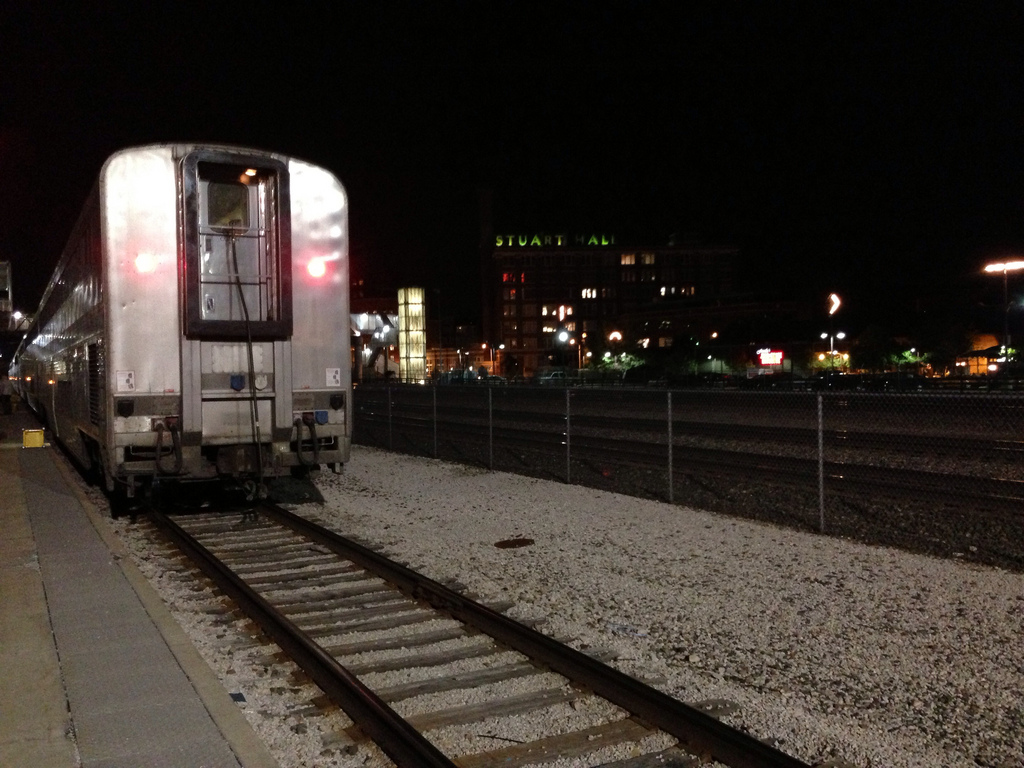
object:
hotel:
[476, 219, 748, 385]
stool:
[16, 421, 51, 454]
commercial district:
[351, 215, 1021, 392]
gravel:
[74, 449, 1021, 766]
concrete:
[132, 524, 284, 626]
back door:
[175, 150, 294, 453]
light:
[392, 276, 435, 393]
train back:
[101, 145, 356, 522]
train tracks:
[101, 505, 848, 766]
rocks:
[297, 586, 738, 766]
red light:
[127, 244, 164, 285]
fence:
[354, 376, 1020, 592]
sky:
[0, 0, 1021, 338]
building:
[473, 209, 736, 382]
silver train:
[19, 144, 351, 503]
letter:
[484, 229, 627, 249]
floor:
[3, 560, 167, 765]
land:
[583, 564, 1018, 684]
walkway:
[3, 537, 204, 761]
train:
[24, 125, 375, 513]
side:
[8, 191, 111, 483]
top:
[329, 347, 1019, 442]